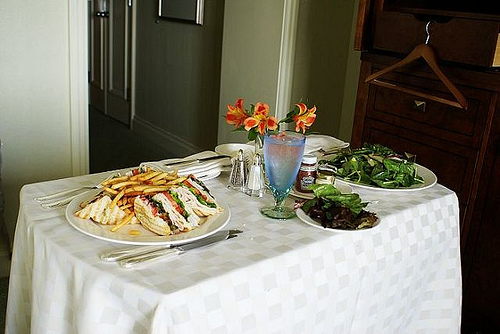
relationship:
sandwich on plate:
[135, 173, 217, 227] [66, 173, 236, 236]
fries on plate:
[107, 166, 176, 190] [66, 173, 236, 236]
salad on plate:
[354, 152, 402, 176] [336, 144, 439, 196]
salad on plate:
[320, 194, 350, 214] [301, 187, 382, 235]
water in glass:
[274, 141, 295, 189] [260, 126, 304, 226]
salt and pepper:
[252, 149, 264, 197] [225, 144, 247, 192]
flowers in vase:
[226, 91, 309, 137] [253, 134, 275, 170]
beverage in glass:
[274, 141, 295, 189] [260, 126, 304, 226]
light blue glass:
[279, 148, 286, 157] [260, 126, 304, 226]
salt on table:
[252, 149, 264, 197] [11, 135, 490, 313]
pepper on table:
[225, 144, 247, 192] [11, 135, 490, 313]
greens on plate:
[354, 152, 402, 176] [336, 144, 439, 196]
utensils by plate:
[38, 168, 126, 193] [66, 173, 236, 236]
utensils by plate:
[102, 226, 250, 254] [66, 173, 236, 236]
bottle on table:
[296, 153, 317, 196] [11, 135, 490, 313]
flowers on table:
[226, 91, 309, 137] [11, 135, 490, 313]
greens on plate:
[349, 145, 376, 171] [336, 144, 439, 196]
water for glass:
[274, 141, 295, 189] [260, 126, 304, 226]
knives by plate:
[89, 226, 257, 270] [66, 173, 236, 236]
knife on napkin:
[165, 147, 245, 167] [142, 148, 232, 176]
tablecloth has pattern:
[83, 271, 471, 328] [386, 225, 419, 261]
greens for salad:
[349, 145, 376, 171] [354, 152, 402, 176]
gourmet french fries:
[109, 168, 168, 202] [107, 166, 176, 190]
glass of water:
[260, 126, 304, 226] [274, 141, 295, 189]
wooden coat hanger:
[388, 37, 444, 65] [361, 33, 480, 120]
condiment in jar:
[296, 153, 317, 196] [298, 150, 314, 187]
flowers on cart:
[226, 91, 309, 137] [11, 135, 490, 313]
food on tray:
[62, 146, 421, 213] [11, 135, 490, 313]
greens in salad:
[349, 145, 376, 171] [354, 152, 402, 176]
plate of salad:
[66, 173, 236, 236] [354, 152, 402, 176]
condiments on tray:
[300, 155, 335, 191] [281, 168, 353, 206]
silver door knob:
[99, 10, 109, 24] [92, 8, 101, 19]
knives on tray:
[89, 226, 257, 270] [18, 175, 481, 261]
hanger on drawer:
[361, 33, 480, 120] [366, 5, 498, 74]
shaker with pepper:
[227, 160, 245, 191] [225, 144, 247, 192]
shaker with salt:
[250, 154, 259, 195] [252, 149, 264, 197]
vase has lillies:
[253, 134, 275, 170] [226, 91, 309, 137]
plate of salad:
[336, 144, 439, 196] [354, 152, 402, 176]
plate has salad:
[301, 187, 382, 235] [320, 194, 350, 214]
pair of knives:
[92, 228, 257, 253] [89, 226, 257, 270]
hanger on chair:
[361, 33, 480, 120] [357, 28, 486, 159]